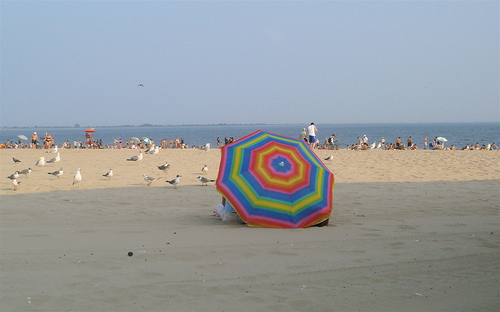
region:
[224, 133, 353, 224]
the umbrela is blue and yellow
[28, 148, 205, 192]
the birds are on the sand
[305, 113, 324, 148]
he has a white top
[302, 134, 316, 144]
the shirt is blue and black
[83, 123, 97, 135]
the umbrella is orange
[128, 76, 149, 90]
the bird is in the sky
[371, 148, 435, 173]
footprints are in the sand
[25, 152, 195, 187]
the birds are black and grey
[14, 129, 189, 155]
people are enjoying the sun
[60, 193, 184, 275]
the beach is full of sand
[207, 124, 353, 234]
Multi-colored beach umbrella.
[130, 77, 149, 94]
Gray object in the sky.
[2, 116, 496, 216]
People at the beach.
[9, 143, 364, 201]
Gray and white seagulls.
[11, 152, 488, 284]
Flat golden sand.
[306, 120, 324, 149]
Man in white shirt.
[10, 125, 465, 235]
Lots of different color umbrellas.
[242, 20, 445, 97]
Dreary blue cloudless sky.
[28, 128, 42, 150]
Man without a shirt on.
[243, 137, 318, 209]
The colors green, red, blue, pink and yellow.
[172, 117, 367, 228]
Rainbow striped umbrella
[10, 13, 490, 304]
Photo taken during the day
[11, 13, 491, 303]
Scene takes place at a beach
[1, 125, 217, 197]
Seagulls on the beach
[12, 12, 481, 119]
The sky is hazy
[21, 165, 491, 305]
Shaded area of the beach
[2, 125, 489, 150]
People in the sun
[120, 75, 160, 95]
A bird in the sky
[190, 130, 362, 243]
People under an umbrella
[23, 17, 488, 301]
Photo taken in the summer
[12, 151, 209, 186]
flock of seagulls on the beach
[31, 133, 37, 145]
man in black trunks on the seashore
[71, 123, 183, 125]
island in the distant on the water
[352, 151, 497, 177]
sand in the sunshine on the beach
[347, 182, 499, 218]
sand in the shade on the beach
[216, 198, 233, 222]
person under umbrella on the beach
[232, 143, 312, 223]
large rainbow umbrella on the beach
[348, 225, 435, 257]
foot prints in the sand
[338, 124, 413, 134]
the ocean at the beach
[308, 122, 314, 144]
man in t shirt and trunks at the seashore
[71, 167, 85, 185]
White bird on the sand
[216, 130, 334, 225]
Large umbrella on the sand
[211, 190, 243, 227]
Person sitting under a large umbrella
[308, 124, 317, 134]
Man with a white shirt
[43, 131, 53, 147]
Woman wearing a black bikini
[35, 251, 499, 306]
Sand on a beach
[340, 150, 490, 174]
Sun shining on sand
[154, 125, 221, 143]
Water in the ocean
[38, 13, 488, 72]
Grey sky above an ocean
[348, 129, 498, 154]
People sitting and standing on a beach